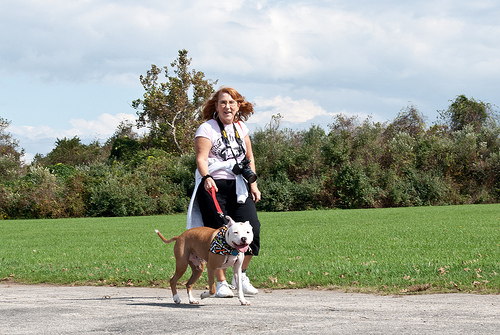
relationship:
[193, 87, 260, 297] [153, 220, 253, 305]
woman walking pitt bull